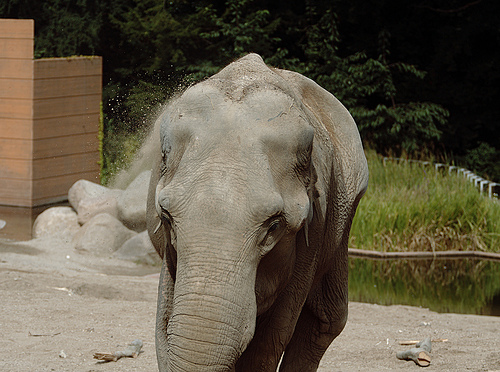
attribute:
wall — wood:
[2, 20, 103, 240]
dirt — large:
[63, 324, 483, 372]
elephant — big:
[125, 68, 384, 372]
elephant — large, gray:
[126, 65, 342, 372]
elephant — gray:
[124, 55, 364, 372]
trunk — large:
[155, 221, 253, 372]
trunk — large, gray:
[162, 242, 256, 368]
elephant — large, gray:
[75, 20, 401, 370]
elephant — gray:
[107, 21, 404, 368]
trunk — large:
[123, 220, 285, 368]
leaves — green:
[366, 74, 447, 176]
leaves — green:
[344, 16, 485, 196]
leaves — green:
[298, 3, 441, 154]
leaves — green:
[175, 0, 374, 80]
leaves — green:
[88, 19, 240, 101]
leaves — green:
[108, 5, 240, 100]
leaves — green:
[0, 0, 146, 81]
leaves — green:
[107, 0, 215, 100]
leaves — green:
[143, 27, 255, 90]